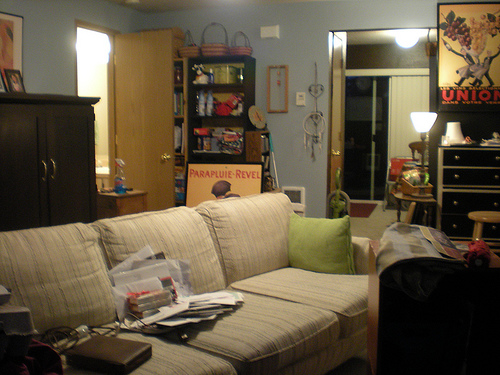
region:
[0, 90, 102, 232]
a dark brown hutch with two doors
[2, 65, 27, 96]
a picture frame sitting upright on a hutch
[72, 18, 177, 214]
a light brown wooden door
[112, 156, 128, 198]
a Windex spray bottle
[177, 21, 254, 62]
three woven brown striped baskets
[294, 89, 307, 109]
a white thermostat mounted on a wall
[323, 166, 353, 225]
a vacuum cleaner with a green handle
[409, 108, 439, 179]
a bright free standing lamp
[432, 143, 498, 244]
a black and grey dresser with drawers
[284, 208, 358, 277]
a green fluffy looking pillow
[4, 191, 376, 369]
a light tan couch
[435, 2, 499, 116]
a framed art poster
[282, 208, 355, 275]
a light green throw pillow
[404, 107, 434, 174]
a lit floor lamp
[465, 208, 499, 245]
a brown wooden stool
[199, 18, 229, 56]
a light pink basket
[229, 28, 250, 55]
a light pink basket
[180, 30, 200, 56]
a light pink basket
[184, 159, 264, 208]
a framed art print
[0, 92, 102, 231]
a dark wood dresser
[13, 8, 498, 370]
Picture taken indoors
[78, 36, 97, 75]
The bathroom light is on.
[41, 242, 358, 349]
A beige sofa in the livingroom.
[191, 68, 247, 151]
A tall book shelf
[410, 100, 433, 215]
A tall floor lamp.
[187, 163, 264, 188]
A large poster is off the wall.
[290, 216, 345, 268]
A green pillow on the sofa.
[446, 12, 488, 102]
A poster with the word Union.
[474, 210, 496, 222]
A wood chair.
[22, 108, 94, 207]
A brown wooden TV stand.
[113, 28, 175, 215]
the wooden door to the room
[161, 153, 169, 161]
the shiny door knob on the door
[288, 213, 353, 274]
the green pillow on the sofa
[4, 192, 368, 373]
the light colored sofa in the room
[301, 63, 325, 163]
the dream catcher hanging on the wall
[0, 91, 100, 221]
the black amoire near the door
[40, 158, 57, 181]
the handles on the doors of the black amoire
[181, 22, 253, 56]
the baskets at the very top of the book shelf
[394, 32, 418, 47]
the ceiling light turned on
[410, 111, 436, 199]
the table lamp turned on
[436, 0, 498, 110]
post on wall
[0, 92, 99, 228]
dark brown dresser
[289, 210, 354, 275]
small green sofa pillow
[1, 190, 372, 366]
a striped three cushion couch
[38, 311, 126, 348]
black cords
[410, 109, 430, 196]
a small table lamp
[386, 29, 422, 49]
light globe in hallway that's lit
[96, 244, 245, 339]
paper clutter on couch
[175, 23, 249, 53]
baskets on top of bookshelf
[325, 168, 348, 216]
a green vacuum cleaner